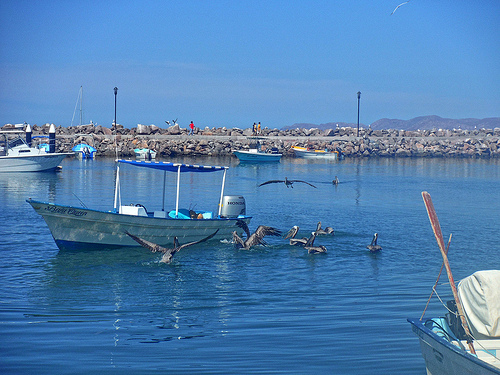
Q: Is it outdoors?
A: Yes, it is outdoors.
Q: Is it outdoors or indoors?
A: It is outdoors.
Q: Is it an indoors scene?
A: No, it is outdoors.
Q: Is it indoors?
A: No, it is outdoors.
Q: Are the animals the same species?
A: Yes, all the animals are birds.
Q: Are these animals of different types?
A: No, all the animals are birds.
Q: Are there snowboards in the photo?
A: No, there are no snowboards.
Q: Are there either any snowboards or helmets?
A: No, there are no snowboards or helmets.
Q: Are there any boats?
A: Yes, there is a boat.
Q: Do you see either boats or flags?
A: Yes, there is a boat.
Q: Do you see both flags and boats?
A: No, there is a boat but no flags.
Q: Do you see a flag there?
A: No, there are no flags.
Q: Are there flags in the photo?
A: No, there are no flags.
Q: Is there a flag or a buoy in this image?
A: No, there are no flags or buoys.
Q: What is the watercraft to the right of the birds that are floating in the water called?
A: The watercraft is a boat.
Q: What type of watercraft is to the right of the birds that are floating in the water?
A: The watercraft is a boat.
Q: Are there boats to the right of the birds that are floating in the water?
A: Yes, there is a boat to the right of the birds.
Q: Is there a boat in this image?
A: Yes, there is a boat.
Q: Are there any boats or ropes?
A: Yes, there is a boat.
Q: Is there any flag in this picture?
A: No, there are no flags.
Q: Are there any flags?
A: No, there are no flags.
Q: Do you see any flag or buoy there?
A: No, there are no flags or buoys.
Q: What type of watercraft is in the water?
A: The watercraft is a boat.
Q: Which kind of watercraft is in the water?
A: The watercraft is a boat.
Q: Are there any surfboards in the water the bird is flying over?
A: No, there is a boat in the water.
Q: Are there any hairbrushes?
A: No, there are no hairbrushes.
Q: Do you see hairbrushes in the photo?
A: No, there are no hairbrushes.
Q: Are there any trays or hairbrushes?
A: No, there are no hairbrushes or trays.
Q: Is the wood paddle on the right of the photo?
A: Yes, the paddle is on the right of the image.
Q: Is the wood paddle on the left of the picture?
A: No, the oar is on the right of the image.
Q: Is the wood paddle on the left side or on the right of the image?
A: The oar is on the right of the image.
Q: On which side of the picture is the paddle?
A: The paddle is on the right of the image.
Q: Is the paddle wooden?
A: Yes, the paddle is wooden.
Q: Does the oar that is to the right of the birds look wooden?
A: Yes, the paddle is wooden.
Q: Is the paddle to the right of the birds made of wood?
A: Yes, the oar is made of wood.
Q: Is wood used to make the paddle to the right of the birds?
A: Yes, the oar is made of wood.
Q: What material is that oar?
A: The oar is made of wood.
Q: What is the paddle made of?
A: The oar is made of wood.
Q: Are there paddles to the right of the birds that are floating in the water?
A: Yes, there is a paddle to the right of the birds.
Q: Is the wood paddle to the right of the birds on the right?
A: Yes, the oar is to the right of the birds.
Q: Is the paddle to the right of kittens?
A: No, the paddle is to the right of the birds.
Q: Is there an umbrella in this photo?
A: No, there are no umbrellas.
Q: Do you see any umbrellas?
A: No, there are no umbrellas.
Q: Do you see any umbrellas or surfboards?
A: No, there are no umbrellas or surfboards.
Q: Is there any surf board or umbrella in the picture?
A: No, there are no umbrellas or surfboards.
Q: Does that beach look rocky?
A: Yes, the beach is rocky.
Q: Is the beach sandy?
A: No, the beach is rocky.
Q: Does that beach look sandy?
A: No, the beach is rocky.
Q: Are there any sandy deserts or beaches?
A: No, there is a beach but it is rocky.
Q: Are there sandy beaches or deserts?
A: No, there is a beach but it is rocky.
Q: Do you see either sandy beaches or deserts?
A: No, there is a beach but it is rocky.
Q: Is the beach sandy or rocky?
A: The beach is rocky.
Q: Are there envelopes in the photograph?
A: No, there are no envelopes.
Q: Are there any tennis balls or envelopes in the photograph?
A: No, there are no envelopes or tennis balls.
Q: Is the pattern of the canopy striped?
A: Yes, the canopy is striped.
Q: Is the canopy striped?
A: Yes, the canopy is striped.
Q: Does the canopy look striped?
A: Yes, the canopy is striped.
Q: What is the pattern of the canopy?
A: The canopy is striped.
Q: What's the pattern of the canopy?
A: The canopy is striped.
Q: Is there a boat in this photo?
A: Yes, there is a boat.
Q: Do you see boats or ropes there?
A: Yes, there is a boat.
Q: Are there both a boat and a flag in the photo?
A: No, there is a boat but no flags.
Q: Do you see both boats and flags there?
A: No, there is a boat but no flags.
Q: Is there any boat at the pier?
A: Yes, there is a boat at the pier.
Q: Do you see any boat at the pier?
A: Yes, there is a boat at the pier.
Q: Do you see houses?
A: No, there are no houses.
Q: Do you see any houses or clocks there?
A: No, there are no houses or clocks.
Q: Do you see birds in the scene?
A: Yes, there is a bird.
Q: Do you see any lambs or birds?
A: Yes, there is a bird.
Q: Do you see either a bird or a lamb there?
A: Yes, there is a bird.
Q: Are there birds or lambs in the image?
A: Yes, there is a bird.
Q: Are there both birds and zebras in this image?
A: No, there is a bird but no zebras.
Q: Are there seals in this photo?
A: No, there are no seals.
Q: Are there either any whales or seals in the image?
A: No, there are no seals or whales.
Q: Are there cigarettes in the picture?
A: No, there are no cigarettes.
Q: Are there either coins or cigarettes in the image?
A: No, there are no cigarettes or coins.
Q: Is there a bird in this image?
A: Yes, there are birds.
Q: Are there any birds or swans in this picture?
A: Yes, there are birds.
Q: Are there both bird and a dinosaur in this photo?
A: No, there are birds but no dinosaurs.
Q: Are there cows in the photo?
A: No, there are no cows.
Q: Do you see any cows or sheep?
A: No, there are no cows or sheep.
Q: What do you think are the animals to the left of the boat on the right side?
A: The animals are birds.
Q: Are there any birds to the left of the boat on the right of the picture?
A: Yes, there are birds to the left of the boat.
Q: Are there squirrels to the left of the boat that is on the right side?
A: No, there are birds to the left of the boat.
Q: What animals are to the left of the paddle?
A: The animals are birds.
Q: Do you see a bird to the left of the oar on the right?
A: Yes, there are birds to the left of the paddle.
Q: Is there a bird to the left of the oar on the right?
A: Yes, there are birds to the left of the paddle.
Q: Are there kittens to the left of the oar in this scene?
A: No, there are birds to the left of the oar.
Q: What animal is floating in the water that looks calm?
A: The birds are floating in the water.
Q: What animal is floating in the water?
A: The birds are floating in the water.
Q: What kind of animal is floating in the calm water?
A: The animals are birds.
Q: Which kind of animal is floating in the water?
A: The animals are birds.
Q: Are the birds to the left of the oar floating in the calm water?
A: Yes, the birds are floating in the water.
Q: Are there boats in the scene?
A: Yes, there is a boat.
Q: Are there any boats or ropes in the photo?
A: Yes, there is a boat.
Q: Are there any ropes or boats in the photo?
A: Yes, there is a boat.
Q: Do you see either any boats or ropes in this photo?
A: Yes, there is a boat.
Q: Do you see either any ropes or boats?
A: Yes, there is a boat.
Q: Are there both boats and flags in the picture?
A: No, there is a boat but no flags.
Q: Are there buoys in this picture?
A: No, there are no buoys.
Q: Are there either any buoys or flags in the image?
A: No, there are no buoys or flags.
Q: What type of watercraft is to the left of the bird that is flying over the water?
A: The watercraft is a boat.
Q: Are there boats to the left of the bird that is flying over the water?
A: Yes, there is a boat to the left of the bird.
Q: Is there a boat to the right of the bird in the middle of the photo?
A: No, the boat is to the left of the bird.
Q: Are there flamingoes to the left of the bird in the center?
A: No, there is a boat to the left of the bird.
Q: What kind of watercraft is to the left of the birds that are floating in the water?
A: The watercraft is a boat.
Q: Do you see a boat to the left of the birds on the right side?
A: Yes, there is a boat to the left of the birds.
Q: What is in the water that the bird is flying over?
A: The boat is in the water.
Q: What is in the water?
A: The boat is in the water.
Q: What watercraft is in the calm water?
A: The watercraft is a boat.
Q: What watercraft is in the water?
A: The watercraft is a boat.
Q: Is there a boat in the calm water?
A: Yes, there is a boat in the water.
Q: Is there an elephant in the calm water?
A: No, there is a boat in the water.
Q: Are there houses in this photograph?
A: No, there are no houses.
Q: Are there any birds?
A: Yes, there is a bird.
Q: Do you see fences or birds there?
A: Yes, there is a bird.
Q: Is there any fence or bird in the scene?
A: Yes, there is a bird.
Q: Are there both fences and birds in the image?
A: No, there is a bird but no fences.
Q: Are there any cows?
A: No, there are no cows.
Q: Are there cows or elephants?
A: No, there are no cows or elephants.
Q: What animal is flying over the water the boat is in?
A: The bird is flying over the water.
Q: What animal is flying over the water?
A: The bird is flying over the water.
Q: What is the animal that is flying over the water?
A: The animal is a bird.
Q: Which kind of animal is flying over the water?
A: The animal is a bird.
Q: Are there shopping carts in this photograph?
A: No, there are no shopping carts.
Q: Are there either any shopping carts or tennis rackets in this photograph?
A: No, there are no shopping carts or tennis rackets.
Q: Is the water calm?
A: Yes, the water is calm.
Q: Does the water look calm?
A: Yes, the water is calm.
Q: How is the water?
A: The water is calm.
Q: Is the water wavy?
A: No, the water is calm.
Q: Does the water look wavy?
A: No, the water is calm.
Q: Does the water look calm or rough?
A: The water is calm.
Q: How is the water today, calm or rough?
A: The water is calm.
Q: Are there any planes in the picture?
A: No, there are no planes.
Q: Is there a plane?
A: No, there are no airplanes.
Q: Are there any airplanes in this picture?
A: No, there are no airplanes.